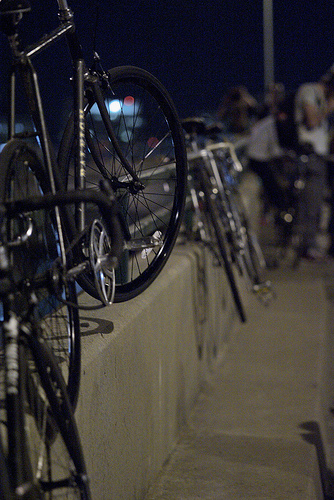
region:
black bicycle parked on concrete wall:
[0, 0, 197, 498]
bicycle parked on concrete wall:
[172, 113, 277, 332]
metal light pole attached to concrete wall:
[258, 0, 280, 174]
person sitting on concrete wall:
[238, 95, 305, 229]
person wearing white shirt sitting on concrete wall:
[294, 65, 332, 171]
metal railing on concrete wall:
[0, 110, 333, 353]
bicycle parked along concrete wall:
[268, 138, 332, 273]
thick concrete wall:
[0, 140, 333, 498]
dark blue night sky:
[0, 0, 332, 113]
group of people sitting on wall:
[241, 60, 332, 236]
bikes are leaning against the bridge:
[178, 115, 279, 329]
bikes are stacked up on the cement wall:
[4, 4, 186, 485]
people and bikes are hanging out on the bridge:
[234, 80, 333, 221]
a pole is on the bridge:
[255, 0, 285, 143]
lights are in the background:
[9, 77, 163, 167]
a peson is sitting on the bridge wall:
[249, 105, 295, 228]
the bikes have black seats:
[178, 112, 225, 140]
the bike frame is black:
[14, 26, 90, 243]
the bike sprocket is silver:
[86, 216, 121, 308]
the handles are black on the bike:
[7, 179, 131, 261]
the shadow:
[307, 432, 316, 458]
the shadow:
[305, 412, 314, 447]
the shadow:
[295, 412, 313, 455]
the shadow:
[309, 428, 312, 455]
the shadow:
[304, 432, 323, 466]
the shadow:
[313, 424, 328, 473]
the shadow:
[313, 425, 320, 455]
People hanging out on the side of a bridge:
[218, 67, 332, 264]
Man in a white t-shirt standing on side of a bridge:
[284, 63, 332, 267]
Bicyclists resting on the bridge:
[246, 64, 333, 262]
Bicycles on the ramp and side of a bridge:
[0, 0, 277, 498]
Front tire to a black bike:
[55, 65, 188, 303]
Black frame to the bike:
[0, 20, 145, 254]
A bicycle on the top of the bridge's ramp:
[1, 1, 188, 417]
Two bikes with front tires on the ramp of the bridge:
[184, 116, 277, 323]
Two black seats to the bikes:
[183, 117, 224, 134]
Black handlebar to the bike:
[8, 177, 131, 261]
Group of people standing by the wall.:
[209, 75, 329, 255]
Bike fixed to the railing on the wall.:
[172, 106, 280, 324]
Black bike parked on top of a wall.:
[0, 3, 188, 399]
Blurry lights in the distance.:
[102, 90, 163, 147]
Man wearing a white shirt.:
[289, 64, 332, 154]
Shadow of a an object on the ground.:
[293, 409, 333, 489]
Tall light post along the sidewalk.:
[258, 0, 284, 106]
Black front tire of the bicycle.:
[53, 62, 189, 306]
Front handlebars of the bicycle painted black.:
[0, 181, 137, 280]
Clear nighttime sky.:
[121, 3, 250, 57]